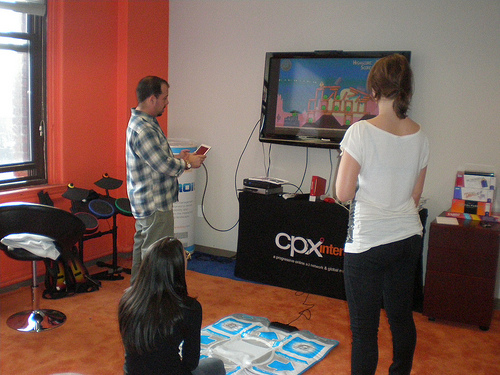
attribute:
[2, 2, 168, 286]
wall — orange, bright orange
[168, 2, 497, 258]
wall — white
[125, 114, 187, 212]
man's shirt — flannel, blue, plaid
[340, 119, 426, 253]
woman's shirt — white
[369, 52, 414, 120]
woman's hair — dark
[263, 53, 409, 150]
tv — black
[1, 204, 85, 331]
chair — leather, black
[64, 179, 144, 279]
drumset — black, colorful, electronic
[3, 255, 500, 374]
carpet — orange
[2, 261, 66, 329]
base on chair — chrome, silver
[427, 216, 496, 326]
stand — wood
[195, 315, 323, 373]
game — blue, gold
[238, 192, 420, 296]
table cloth — black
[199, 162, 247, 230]
cable — black